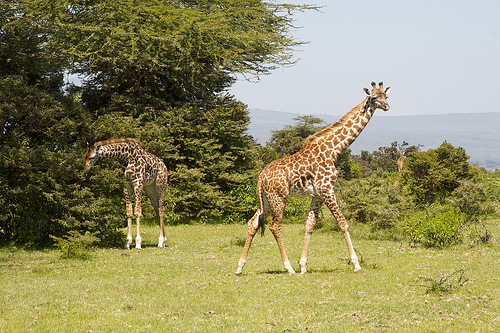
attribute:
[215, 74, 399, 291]
giraffe — wild, looking, walking, standing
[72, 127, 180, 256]
giraffe — eating, wild, standing, bending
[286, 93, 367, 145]
mane — brown, white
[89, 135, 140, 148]
mane — brown, white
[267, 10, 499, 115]
sky — blue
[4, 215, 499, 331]
field — brown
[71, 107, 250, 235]
bush — green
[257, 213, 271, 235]
hair — black